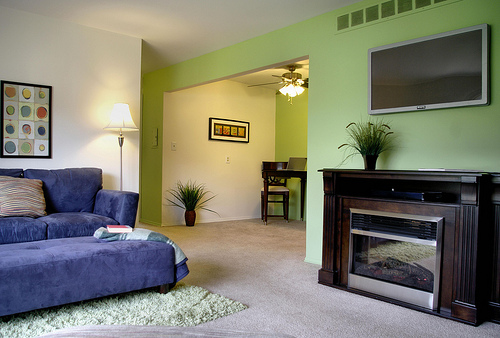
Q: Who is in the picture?
A: No one.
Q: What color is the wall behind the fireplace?
A: Green.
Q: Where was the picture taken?
A: Living room.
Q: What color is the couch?
A: Purple.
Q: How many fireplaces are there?
A: One.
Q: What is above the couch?
A: Painting.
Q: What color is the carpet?
A: Beige.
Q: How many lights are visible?
A: Two.